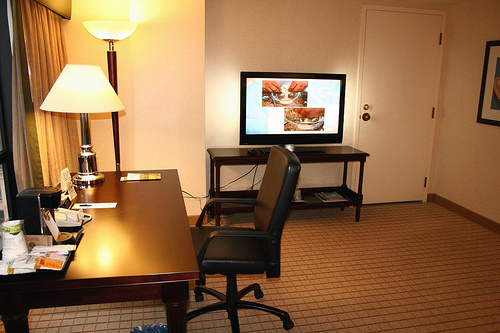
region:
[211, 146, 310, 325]
this is an office chair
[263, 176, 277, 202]
the chair is white in color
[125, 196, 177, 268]
this is a table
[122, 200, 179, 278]
the table is wooden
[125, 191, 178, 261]
the table is brown in color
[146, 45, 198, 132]
this is the wall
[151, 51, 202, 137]
the wall is white in color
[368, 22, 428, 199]
this is a door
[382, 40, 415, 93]
the door is wooden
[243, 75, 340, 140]
this is a television set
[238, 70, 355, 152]
this is a television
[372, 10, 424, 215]
this is a door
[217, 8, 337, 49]
this is the wall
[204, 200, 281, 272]
this is a chair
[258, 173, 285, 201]
the chair is black in color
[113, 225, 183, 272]
this is a table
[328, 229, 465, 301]
this is the floor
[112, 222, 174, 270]
the table is brown in color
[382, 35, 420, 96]
the door is white in color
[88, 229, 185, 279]
the table is wooden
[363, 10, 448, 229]
A white door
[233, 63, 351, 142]
A tv turned on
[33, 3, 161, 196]
Two lamps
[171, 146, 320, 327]
A black desk chair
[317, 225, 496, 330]
Brown carpet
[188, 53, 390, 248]
A tv on an entertainment stand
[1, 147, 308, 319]
A black chair at a desk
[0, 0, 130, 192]
Two lamps in front of curtains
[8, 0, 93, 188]
Brown curtains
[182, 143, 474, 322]
A chair on brown carpet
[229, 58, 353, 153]
television on a table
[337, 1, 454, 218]
door in a room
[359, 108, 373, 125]
knob on a door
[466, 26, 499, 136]
picture on a wall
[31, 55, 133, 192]
lamp on a desk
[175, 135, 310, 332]
chair near a desk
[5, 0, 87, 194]
curtains on a window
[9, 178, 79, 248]
black coffee maker in a tray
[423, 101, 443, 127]
hinge on a door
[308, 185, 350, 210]
magazine on a shelf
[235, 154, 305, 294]
the chair is black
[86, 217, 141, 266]
there is light reflction on the table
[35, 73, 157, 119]
the light is on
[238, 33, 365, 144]
the tv is on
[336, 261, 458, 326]
the floor has square tiles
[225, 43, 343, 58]
the wall is white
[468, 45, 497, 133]
there is photo is on the wall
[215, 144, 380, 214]
the table is made of wood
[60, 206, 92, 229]
the telephone is on the desk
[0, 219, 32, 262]
the cups are white